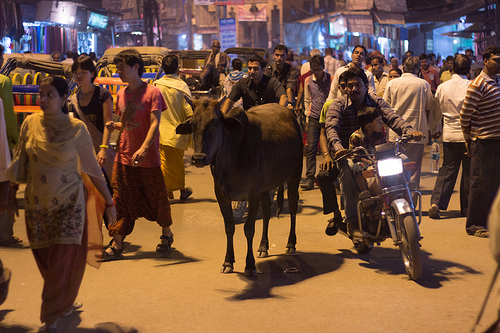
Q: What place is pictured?
A: It is a market.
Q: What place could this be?
A: It is a market.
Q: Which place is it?
A: It is a market.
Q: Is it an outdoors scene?
A: Yes, it is outdoors.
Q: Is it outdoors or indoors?
A: It is outdoors.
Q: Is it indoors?
A: No, it is outdoors.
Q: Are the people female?
A: No, they are both male and female.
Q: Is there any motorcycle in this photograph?
A: Yes, there is a motorcycle.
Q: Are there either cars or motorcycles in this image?
A: Yes, there is a motorcycle.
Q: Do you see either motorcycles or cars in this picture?
A: Yes, there is a motorcycle.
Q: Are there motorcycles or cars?
A: Yes, there is a motorcycle.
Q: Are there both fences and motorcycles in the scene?
A: No, there is a motorcycle but no fences.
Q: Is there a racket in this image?
A: No, there are no rackets.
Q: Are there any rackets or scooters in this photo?
A: No, there are no rackets or scooters.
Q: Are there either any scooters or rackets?
A: No, there are no rackets or scooters.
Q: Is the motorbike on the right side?
A: Yes, the motorbike is on the right of the image.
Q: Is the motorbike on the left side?
A: No, the motorbike is on the right of the image.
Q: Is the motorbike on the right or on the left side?
A: The motorbike is on the right of the image.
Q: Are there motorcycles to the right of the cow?
A: Yes, there is a motorcycle to the right of the cow.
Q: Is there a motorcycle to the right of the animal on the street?
A: Yes, there is a motorcycle to the right of the cow.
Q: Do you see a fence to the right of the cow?
A: No, there is a motorcycle to the right of the cow.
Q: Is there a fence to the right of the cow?
A: No, there is a motorcycle to the right of the cow.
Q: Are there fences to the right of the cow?
A: No, there is a motorcycle to the right of the cow.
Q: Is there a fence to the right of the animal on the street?
A: No, there is a motorcycle to the right of the cow.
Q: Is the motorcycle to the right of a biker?
A: No, the motorcycle is to the right of the cow.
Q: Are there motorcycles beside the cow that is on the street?
A: Yes, there is a motorcycle beside the cow.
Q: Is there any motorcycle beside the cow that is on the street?
A: Yes, there is a motorcycle beside the cow.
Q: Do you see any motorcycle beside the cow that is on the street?
A: Yes, there is a motorcycle beside the cow.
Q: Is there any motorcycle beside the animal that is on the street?
A: Yes, there is a motorcycle beside the cow.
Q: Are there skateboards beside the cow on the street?
A: No, there is a motorcycle beside the cow.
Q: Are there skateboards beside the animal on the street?
A: No, there is a motorcycle beside the cow.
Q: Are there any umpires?
A: No, there are no umpires.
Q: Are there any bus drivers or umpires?
A: No, there are no umpires or bus drivers.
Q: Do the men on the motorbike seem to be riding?
A: Yes, the men are riding.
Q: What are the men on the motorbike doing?
A: The men are riding.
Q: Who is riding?
A: The men are riding.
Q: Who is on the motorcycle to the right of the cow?
A: The men are on the motorcycle.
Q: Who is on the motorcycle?
A: The men are on the motorcycle.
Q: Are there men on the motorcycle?
A: Yes, there are men on the motorcycle.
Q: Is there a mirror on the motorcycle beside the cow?
A: No, there are men on the motorbike.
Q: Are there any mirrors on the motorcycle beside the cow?
A: No, there are men on the motorbike.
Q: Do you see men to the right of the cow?
A: Yes, there are men to the right of the cow.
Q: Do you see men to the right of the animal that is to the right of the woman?
A: Yes, there are men to the right of the cow.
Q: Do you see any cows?
A: Yes, there is a cow.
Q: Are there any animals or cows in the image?
A: Yes, there is a cow.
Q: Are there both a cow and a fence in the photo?
A: No, there is a cow but no fences.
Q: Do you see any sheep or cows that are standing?
A: Yes, the cow is standing.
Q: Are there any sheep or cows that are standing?
A: Yes, the cow is standing.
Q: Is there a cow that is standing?
A: Yes, there is a cow that is standing.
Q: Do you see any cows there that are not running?
A: Yes, there is a cow that is standing .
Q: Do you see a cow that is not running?
A: Yes, there is a cow that is standing .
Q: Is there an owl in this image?
A: No, there are no owls.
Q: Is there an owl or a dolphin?
A: No, there are no owls or dolphins.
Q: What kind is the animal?
A: The animal is a cow.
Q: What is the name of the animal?
A: The animal is a cow.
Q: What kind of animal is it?
A: The animal is a cow.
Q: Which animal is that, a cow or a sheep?
A: This is a cow.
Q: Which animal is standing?
A: The animal is a cow.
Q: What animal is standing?
A: The animal is a cow.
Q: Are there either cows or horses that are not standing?
A: No, there is a cow but it is standing.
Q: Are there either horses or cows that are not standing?
A: No, there is a cow but it is standing.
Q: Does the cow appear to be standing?
A: Yes, the cow is standing.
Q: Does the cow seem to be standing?
A: Yes, the cow is standing.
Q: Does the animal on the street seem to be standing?
A: Yes, the cow is standing.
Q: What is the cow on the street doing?
A: The cow is standing.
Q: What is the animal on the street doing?
A: The cow is standing.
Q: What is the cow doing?
A: The cow is standing.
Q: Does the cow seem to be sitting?
A: No, the cow is standing.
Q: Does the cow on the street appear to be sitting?
A: No, the cow is standing.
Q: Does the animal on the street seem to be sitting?
A: No, the cow is standing.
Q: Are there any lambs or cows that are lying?
A: No, there is a cow but it is standing.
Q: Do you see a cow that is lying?
A: No, there is a cow but it is standing.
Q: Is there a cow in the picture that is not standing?
A: No, there is a cow but it is standing.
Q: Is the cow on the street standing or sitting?
A: The cow is standing.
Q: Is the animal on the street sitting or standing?
A: The cow is standing.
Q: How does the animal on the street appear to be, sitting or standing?
A: The cow is standing.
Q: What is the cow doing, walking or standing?
A: The cow is standing.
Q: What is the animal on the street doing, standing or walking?
A: The cow is standing.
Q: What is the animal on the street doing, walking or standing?
A: The cow is standing.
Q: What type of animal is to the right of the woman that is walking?
A: The animal is a cow.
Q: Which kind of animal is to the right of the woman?
A: The animal is a cow.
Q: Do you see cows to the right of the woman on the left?
A: Yes, there is a cow to the right of the woman.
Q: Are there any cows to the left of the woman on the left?
A: No, the cow is to the right of the woman.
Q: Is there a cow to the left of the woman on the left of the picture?
A: No, the cow is to the right of the woman.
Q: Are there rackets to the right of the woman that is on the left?
A: No, there is a cow to the right of the woman.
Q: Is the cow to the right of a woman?
A: Yes, the cow is to the right of a woman.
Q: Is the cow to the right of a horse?
A: No, the cow is to the right of a woman.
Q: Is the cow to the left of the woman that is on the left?
A: No, the cow is to the right of the woman.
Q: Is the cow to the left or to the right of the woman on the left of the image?
A: The cow is to the right of the woman.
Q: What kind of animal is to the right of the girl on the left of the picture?
A: The animal is a cow.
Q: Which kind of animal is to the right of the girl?
A: The animal is a cow.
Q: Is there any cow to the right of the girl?
A: Yes, there is a cow to the right of the girl.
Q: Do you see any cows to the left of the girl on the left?
A: No, the cow is to the right of the girl.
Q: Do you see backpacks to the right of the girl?
A: No, there is a cow to the right of the girl.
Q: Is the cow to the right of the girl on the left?
A: Yes, the cow is to the right of the girl.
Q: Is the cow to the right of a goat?
A: No, the cow is to the right of the girl.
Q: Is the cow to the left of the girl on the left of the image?
A: No, the cow is to the right of the girl.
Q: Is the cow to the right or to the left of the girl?
A: The cow is to the right of the girl.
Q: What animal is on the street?
A: The animal is a cow.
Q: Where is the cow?
A: The cow is on the street.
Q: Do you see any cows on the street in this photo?
A: Yes, there is a cow on the street.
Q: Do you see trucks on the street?
A: No, there is a cow on the street.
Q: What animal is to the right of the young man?
A: The animal is a cow.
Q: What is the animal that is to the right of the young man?
A: The animal is a cow.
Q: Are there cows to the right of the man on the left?
A: Yes, there is a cow to the right of the man.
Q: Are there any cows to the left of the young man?
A: No, the cow is to the right of the man.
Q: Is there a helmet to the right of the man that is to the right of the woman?
A: No, there is a cow to the right of the man.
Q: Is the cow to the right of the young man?
A: Yes, the cow is to the right of the man.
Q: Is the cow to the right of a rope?
A: No, the cow is to the right of the man.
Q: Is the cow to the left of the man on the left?
A: No, the cow is to the right of the man.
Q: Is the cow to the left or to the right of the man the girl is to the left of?
A: The cow is to the right of the man.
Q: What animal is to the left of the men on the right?
A: The animal is a cow.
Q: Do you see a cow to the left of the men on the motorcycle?
A: Yes, there is a cow to the left of the men.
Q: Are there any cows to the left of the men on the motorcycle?
A: Yes, there is a cow to the left of the men.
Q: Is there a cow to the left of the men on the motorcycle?
A: Yes, there is a cow to the left of the men.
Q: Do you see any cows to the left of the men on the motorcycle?
A: Yes, there is a cow to the left of the men.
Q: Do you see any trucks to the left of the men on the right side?
A: No, there is a cow to the left of the men.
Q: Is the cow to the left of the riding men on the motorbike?
A: Yes, the cow is to the left of the men.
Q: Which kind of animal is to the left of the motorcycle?
A: The animal is a cow.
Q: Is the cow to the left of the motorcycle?
A: Yes, the cow is to the left of the motorcycle.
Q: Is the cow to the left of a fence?
A: No, the cow is to the left of the motorcycle.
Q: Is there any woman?
A: Yes, there is a woman.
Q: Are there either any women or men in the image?
A: Yes, there is a woman.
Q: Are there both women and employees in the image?
A: No, there is a woman but no employees.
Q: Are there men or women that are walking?
A: Yes, the woman is walking.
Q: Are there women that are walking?
A: Yes, there is a woman that is walking.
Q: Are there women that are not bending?
A: Yes, there is a woman that is walking.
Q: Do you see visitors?
A: No, there are no visitors.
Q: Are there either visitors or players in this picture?
A: No, there are no visitors or players.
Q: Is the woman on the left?
A: Yes, the woman is on the left of the image.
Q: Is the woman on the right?
A: No, the woman is on the left of the image.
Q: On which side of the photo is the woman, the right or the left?
A: The woman is on the left of the image.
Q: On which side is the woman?
A: The woman is on the left of the image.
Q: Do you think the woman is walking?
A: Yes, the woman is walking.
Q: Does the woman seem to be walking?
A: Yes, the woman is walking.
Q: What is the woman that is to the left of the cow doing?
A: The woman is walking.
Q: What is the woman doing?
A: The woman is walking.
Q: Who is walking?
A: The woman is walking.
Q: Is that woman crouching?
A: No, the woman is walking.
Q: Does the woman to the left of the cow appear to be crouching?
A: No, the woman is walking.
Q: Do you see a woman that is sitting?
A: No, there is a woman but she is walking.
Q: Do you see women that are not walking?
A: No, there is a woman but she is walking.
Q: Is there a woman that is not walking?
A: No, there is a woman but she is walking.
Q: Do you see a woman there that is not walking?
A: No, there is a woman but she is walking.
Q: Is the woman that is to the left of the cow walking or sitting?
A: The woman is walking.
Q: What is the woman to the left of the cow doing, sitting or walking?
A: The woman is walking.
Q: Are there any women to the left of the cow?
A: Yes, there is a woman to the left of the cow.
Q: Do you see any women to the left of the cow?
A: Yes, there is a woman to the left of the cow.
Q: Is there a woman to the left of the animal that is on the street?
A: Yes, there is a woman to the left of the cow.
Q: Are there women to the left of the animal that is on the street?
A: Yes, there is a woman to the left of the cow.